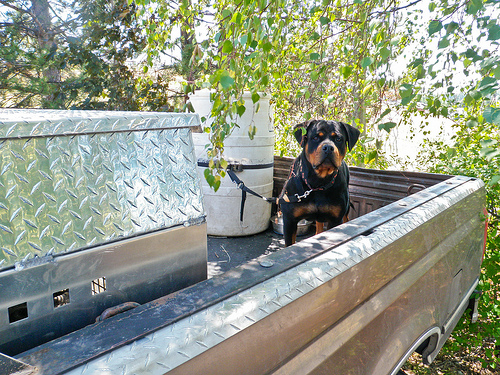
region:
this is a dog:
[260, 86, 380, 254]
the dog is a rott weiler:
[252, 72, 372, 253]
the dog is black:
[263, 103, 379, 262]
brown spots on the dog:
[278, 109, 356, 237]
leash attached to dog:
[197, 146, 327, 210]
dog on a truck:
[14, 8, 497, 365]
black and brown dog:
[264, 96, 388, 207]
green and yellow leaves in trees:
[207, 28, 269, 70]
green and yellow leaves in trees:
[391, 33, 471, 77]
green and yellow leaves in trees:
[165, 12, 215, 42]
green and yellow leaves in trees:
[40, 21, 95, 51]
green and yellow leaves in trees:
[150, 27, 226, 54]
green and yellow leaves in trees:
[190, 42, 235, 78]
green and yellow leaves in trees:
[100, 1, 146, 48]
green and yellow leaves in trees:
[177, 8, 254, 63]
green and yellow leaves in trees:
[255, 26, 320, 76]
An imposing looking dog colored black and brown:
[272, 112, 372, 219]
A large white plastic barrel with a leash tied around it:
[192, 78, 267, 224]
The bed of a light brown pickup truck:
[22, 90, 492, 374]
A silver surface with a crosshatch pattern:
[39, 143, 163, 223]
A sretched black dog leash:
[225, 171, 292, 214]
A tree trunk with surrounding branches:
[22, 2, 69, 107]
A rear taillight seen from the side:
[477, 207, 493, 264]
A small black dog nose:
[320, 143, 335, 156]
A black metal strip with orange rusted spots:
[137, 280, 209, 320]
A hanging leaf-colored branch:
[201, 68, 238, 203]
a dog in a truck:
[267, 101, 422, 337]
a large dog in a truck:
[307, 122, 362, 224]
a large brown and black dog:
[262, 55, 397, 287]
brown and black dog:
[286, 127, 353, 215]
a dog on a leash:
[239, 88, 380, 219]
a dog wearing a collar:
[272, 110, 361, 210]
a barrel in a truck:
[200, 68, 293, 227]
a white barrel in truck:
[200, 53, 275, 220]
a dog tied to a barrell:
[224, 79, 388, 288]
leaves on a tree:
[202, 45, 371, 130]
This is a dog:
[246, 103, 384, 270]